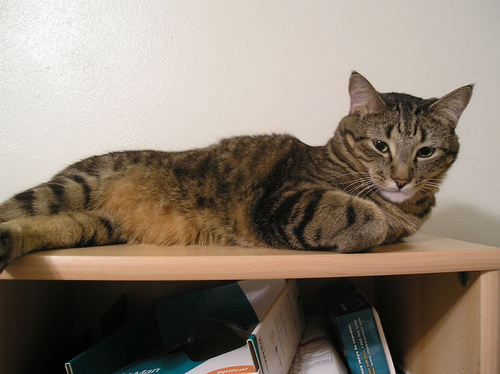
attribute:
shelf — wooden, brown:
[0, 226, 498, 373]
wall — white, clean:
[2, 0, 498, 244]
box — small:
[319, 279, 400, 373]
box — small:
[66, 280, 307, 373]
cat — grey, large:
[0, 70, 475, 272]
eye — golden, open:
[369, 137, 392, 156]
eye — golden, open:
[416, 144, 437, 161]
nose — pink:
[393, 177, 409, 191]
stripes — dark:
[52, 181, 69, 211]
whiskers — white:
[335, 173, 394, 204]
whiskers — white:
[415, 178, 469, 206]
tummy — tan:
[114, 183, 198, 247]